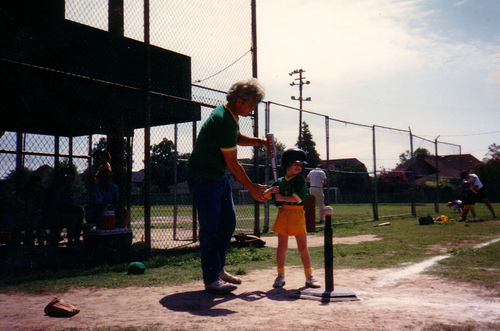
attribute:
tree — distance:
[294, 121, 322, 161]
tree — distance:
[141, 134, 179, 195]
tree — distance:
[144, 134, 189, 196]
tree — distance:
[383, 132, 448, 221]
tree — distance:
[292, 117, 322, 164]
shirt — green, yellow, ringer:
[189, 102, 239, 182]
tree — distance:
[483, 139, 499, 224]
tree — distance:
[152, 131, 175, 178]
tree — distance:
[50, 147, 101, 262]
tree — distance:
[374, 127, 461, 212]